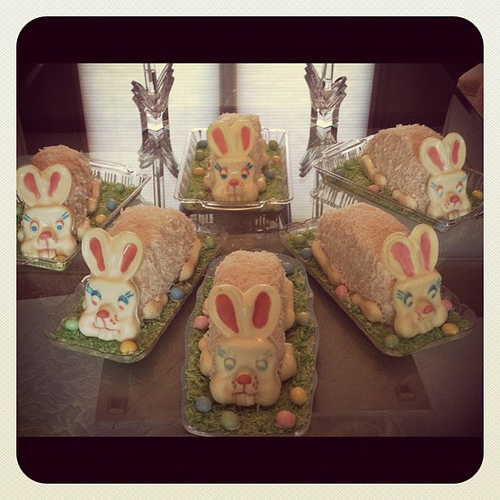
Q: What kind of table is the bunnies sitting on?
A: A marble table.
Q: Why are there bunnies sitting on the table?
A: Because they are there for people to eat.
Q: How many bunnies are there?
A: Six.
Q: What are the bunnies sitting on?
A: A table.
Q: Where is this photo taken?
A: Inside of a dining room.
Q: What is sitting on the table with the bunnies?
A: Glass statues.